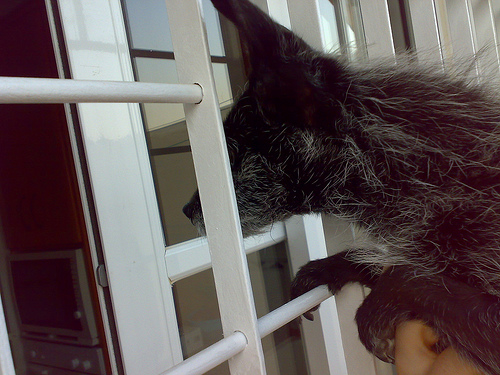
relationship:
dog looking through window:
[155, 10, 499, 348] [48, 36, 306, 366]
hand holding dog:
[388, 316, 469, 373] [170, 0, 498, 375]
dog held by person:
[170, 0, 498, 375] [384, 312, 498, 375]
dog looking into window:
[170, 0, 498, 375] [122, 3, 349, 373]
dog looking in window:
[170, 0, 498, 375] [51, 0, 411, 373]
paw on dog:
[178, 6, 498, 373] [170, 0, 498, 375]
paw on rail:
[178, 6, 498, 373] [151, 263, 362, 372]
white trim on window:
[45, 0, 394, 373] [51, 0, 411, 373]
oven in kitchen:
[5, 247, 108, 372] [4, 1, 111, 372]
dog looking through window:
[170, 0, 498, 375] [117, 1, 308, 373]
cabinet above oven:
[0, 0, 85, 255] [5, 247, 108, 372]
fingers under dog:
[380, 305, 498, 373] [170, 0, 498, 375]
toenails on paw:
[299, 305, 313, 328] [277, 255, 342, 319]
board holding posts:
[166, 24, 299, 373] [175, 37, 293, 374]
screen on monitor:
[5, 258, 91, 331] [12, 247, 107, 360]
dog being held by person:
[170, 0, 498, 375] [353, 260, 498, 372]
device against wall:
[5, 243, 114, 372] [0, 147, 75, 239]